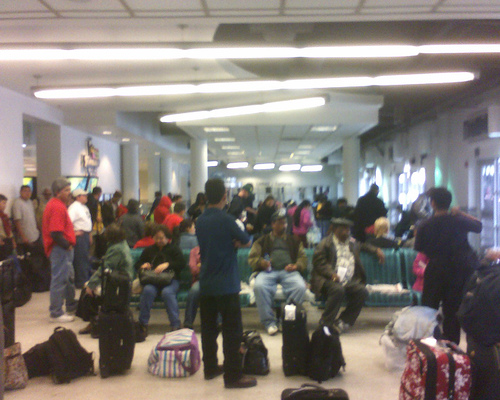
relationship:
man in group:
[44, 176, 81, 322] [45, 174, 383, 351]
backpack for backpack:
[143, 329, 203, 376] [143, 329, 203, 376]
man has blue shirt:
[192, 170, 254, 390] [195, 207, 248, 293]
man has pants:
[192, 170, 254, 390] [190, 283, 248, 383]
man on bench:
[311, 216, 386, 334] [129, 245, 424, 330]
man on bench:
[248, 203, 308, 335] [129, 245, 424, 330]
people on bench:
[183, 245, 200, 327] [129, 245, 424, 330]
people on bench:
[132, 226, 187, 341] [129, 245, 424, 330]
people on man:
[79, 224, 130, 334] [311, 216, 386, 334]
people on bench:
[75, 211, 378, 343] [83, 244, 432, 324]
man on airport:
[192, 170, 254, 390] [2, 3, 499, 398]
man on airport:
[44, 176, 81, 322] [2, 3, 499, 398]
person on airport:
[66, 188, 97, 290] [2, 3, 499, 398]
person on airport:
[412, 184, 484, 347] [2, 3, 499, 398]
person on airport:
[12, 182, 39, 267] [2, 3, 499, 398]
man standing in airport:
[192, 170, 254, 390] [2, 3, 499, 398]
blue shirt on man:
[195, 207, 248, 293] [197, 175, 258, 390]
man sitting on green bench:
[311, 216, 386, 334] [359, 246, 408, 306]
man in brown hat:
[311, 216, 386, 334] [330, 216, 354, 228]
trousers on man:
[324, 280, 364, 337] [308, 210, 378, 331]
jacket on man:
[297, 217, 388, 315] [311, 216, 386, 334]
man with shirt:
[311, 216, 386, 334] [328, 236, 358, 286]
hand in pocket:
[57, 245, 67, 252] [56, 243, 70, 260]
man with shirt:
[44, 176, 81, 322] [40, 197, 75, 249]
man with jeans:
[44, 176, 81, 322] [47, 241, 77, 318]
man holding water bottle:
[255, 203, 308, 281] [262, 251, 275, 274]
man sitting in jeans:
[255, 203, 308, 281] [253, 267, 313, 316]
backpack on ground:
[143, 329, 203, 376] [341, 318, 384, 398]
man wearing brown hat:
[311, 216, 386, 334] [330, 216, 354, 228]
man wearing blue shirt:
[192, 170, 254, 390] [195, 207, 248, 293]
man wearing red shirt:
[44, 176, 81, 322] [36, 197, 88, 257]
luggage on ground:
[308, 321, 346, 383] [340, 315, 394, 397]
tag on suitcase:
[276, 297, 296, 333] [282, 300, 348, 383]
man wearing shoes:
[192, 170, 254, 390] [201, 362, 258, 388]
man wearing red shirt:
[38, 176, 81, 322] [39, 197, 76, 257]